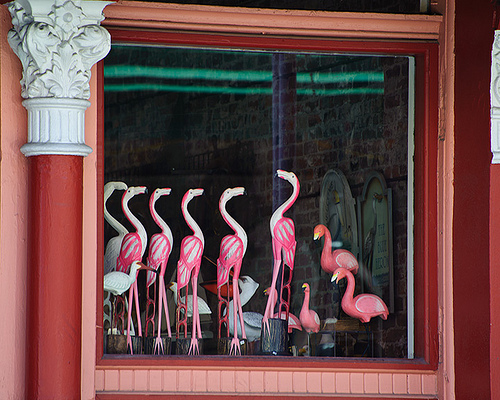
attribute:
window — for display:
[65, 4, 455, 384]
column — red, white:
[3, 2, 125, 397]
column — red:
[29, 165, 80, 350]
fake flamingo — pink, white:
[174, 188, 207, 355]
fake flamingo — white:
[219, 176, 250, 345]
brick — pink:
[91, 366, 447, 398]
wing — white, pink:
[272, 217, 303, 264]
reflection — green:
[103, 59, 386, 99]